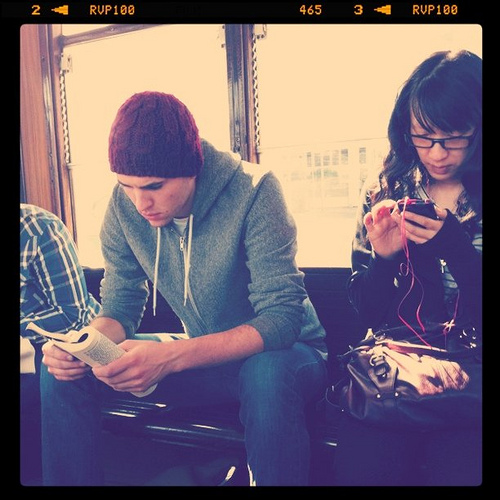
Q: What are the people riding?
A: Train.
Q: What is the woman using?
A: A smartphone.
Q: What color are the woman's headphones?
A: Pink.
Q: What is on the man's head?
A: A knit hat.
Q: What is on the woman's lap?
A: Purse.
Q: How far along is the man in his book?
A: More than halfway.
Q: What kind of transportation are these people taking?
A: Public transportation.